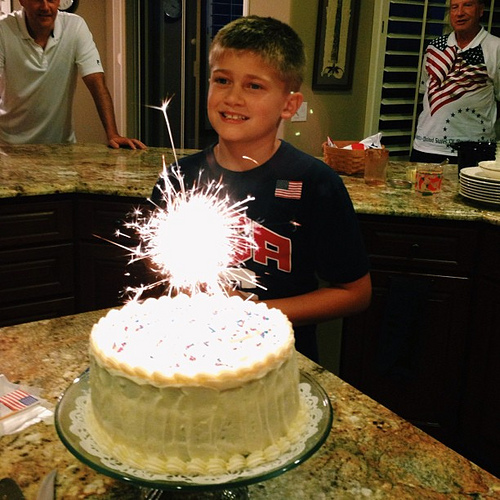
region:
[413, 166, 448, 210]
The glass looks like it has hot peppers on the outside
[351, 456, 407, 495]
The top of the countertop is a deep marble brown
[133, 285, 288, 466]
This cake is a vanilla-frosted cake taking center stage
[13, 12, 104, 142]
This man has a white polo shirt on and is the grandpa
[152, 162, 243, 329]
There is a fiery sparkler candle on top of the cake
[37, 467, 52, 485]
There is a knife for cutting the cake that is on the counter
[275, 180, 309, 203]
The child has a flag on his navy t-shirt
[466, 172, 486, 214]
The plates on the countertop are ivory in color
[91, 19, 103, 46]
There is a beige color that is against the walls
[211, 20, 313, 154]
The child seems to be smiling at the occasion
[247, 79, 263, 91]
the eye of a person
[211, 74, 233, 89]
the eye of a person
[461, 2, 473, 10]
the eye of a person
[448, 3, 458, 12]
the eye of a person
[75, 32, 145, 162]
the hand of a person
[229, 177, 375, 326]
the hand of a person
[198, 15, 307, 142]
the head of a person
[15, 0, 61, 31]
the head of a person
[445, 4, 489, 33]
the head of a person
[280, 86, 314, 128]
the ear of a person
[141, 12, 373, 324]
child is smiling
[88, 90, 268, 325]
sparkler is on fire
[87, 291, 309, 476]
sparkler on white cake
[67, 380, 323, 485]
white doily under white cake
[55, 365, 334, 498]
white cake on glass cake stand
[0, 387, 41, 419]
small American flag next to cake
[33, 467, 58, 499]
knife under cake stand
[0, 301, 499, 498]
cake stand on counter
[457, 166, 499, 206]
pile of white plates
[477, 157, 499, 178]
white bowl on pile of plates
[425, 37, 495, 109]
USA red and blue flag graphic on the white t-shirt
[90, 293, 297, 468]
cake with white icing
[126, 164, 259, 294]
fireworks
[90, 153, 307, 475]
fireworks over a white frosted cake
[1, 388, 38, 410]
USA flag graphic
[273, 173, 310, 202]
USA flag graphic on the blue shirt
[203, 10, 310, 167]
dark hair boy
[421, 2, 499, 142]
man wearing colorful flag graphic shirt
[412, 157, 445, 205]
clear cup with red pepper design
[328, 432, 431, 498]
marble countertop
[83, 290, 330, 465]
a frosted birthday cake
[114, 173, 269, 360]
birthday cake with candles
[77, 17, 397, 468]
a child celebrating his birthday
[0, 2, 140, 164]
a father watching his son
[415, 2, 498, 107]
a man with an american flag shirt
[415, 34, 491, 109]
two american flags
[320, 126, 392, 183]
a basket full of snacks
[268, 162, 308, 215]
an american flag badge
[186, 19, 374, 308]
a kid with an american shirt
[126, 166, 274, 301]
firework candles